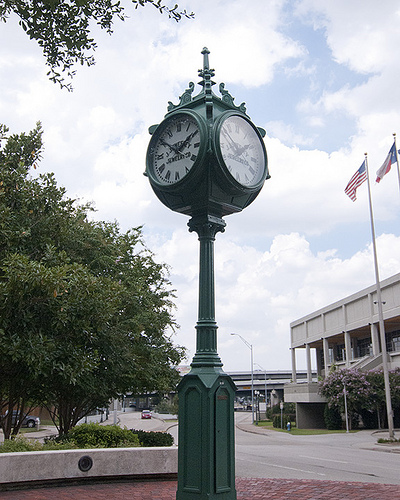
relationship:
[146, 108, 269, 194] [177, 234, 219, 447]
clock on pole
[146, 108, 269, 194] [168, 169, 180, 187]
clock face white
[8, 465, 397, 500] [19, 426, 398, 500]
bricks on ground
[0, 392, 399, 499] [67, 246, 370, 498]
street in area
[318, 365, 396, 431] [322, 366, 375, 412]
tree with leaves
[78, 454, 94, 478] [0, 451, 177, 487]
hole in wall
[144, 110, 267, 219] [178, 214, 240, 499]
clock on pole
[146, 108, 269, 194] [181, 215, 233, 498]
clock on pole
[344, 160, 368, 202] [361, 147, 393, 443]
flag on pole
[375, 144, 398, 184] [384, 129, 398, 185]
flag on pole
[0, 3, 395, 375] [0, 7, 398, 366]
clouds in sky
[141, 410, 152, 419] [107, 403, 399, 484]
car on road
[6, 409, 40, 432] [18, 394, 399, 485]
car on road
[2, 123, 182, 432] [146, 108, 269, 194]
trees near th clock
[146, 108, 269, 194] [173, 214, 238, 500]
clock fitted on clock pillar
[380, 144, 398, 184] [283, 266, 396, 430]
flag next to building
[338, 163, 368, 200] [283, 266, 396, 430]
flag next to building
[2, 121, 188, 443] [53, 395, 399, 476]
tree garden beside road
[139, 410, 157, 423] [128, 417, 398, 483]
car moving on road